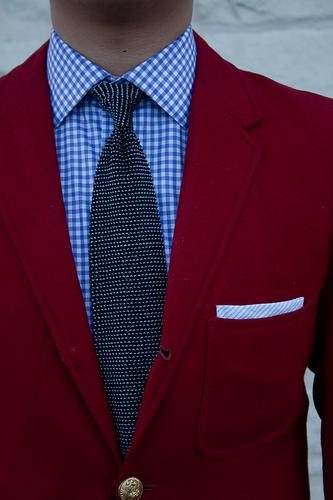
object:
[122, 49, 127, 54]
freckle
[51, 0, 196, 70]
neck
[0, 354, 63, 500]
coat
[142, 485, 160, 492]
hole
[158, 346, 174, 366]
button hole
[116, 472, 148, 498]
button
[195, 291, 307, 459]
pocket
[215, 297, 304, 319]
handkerchief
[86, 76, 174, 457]
tie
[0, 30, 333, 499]
torso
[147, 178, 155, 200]
edge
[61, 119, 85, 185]
part shirt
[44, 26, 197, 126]
collar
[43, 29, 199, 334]
shirt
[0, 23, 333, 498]
jacket